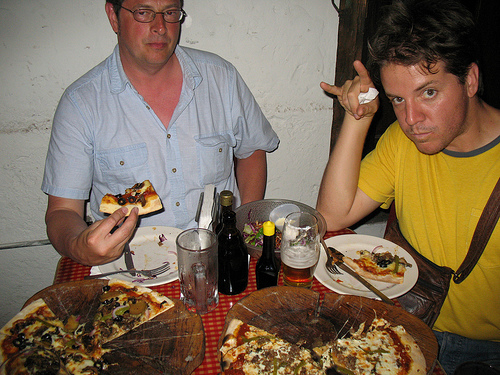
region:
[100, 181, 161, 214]
pizza is half eaten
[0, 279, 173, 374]
some pieces of pizza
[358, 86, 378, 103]
the napkin is white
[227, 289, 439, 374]
pizza tray is black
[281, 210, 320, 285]
a glass of beer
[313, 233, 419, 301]
the plate is white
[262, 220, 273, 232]
the cap is yellow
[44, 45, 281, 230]
shirt is light blue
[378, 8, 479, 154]
man looking at camera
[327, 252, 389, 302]
knife on the plate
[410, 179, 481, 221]
man wearing a yellow shirt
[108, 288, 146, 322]
a slice of pizza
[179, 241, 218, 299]
a clear glass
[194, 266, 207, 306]
handle on the glass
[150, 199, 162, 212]
crust of the pizza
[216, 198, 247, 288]
a black bottle on the table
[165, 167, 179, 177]
button on the shirt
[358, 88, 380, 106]
a white napkin in hand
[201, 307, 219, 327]
the red table cloth on the table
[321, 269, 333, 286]
a white plate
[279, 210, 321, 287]
Glass of beer is mostly empty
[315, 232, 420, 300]
Plate with knife and fork and some half eaten pizza.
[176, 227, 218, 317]
Dirty empty glass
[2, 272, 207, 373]
Vegetable pizza on a wooden cutting board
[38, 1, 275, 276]
Man in a blue shirt is eating pizza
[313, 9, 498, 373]
Man in a yellow shirt is eating pizza and doing a hand gesture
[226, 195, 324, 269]
Metal bowl of salad behind beer glass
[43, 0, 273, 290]
Man is wearing glasses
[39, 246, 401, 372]
Red checkered table cloth under plates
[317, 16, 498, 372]
Man is wearing a brown leather bag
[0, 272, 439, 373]
Two wooden trays of pizza.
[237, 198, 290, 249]
A glass bowl of tossed salad.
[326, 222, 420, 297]
A white dish with half eaten pizza.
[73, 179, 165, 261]
A hand holding a half eaten pizza.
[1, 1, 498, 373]
Two men sitting at a table.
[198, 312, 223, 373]
A red table cloth of plaid design.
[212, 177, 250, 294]
A beverage in a dark bottle.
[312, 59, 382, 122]
A rock and roll hand sign.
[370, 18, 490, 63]
The man's brown curly hair.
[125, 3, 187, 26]
The man's dark rimmer glasses.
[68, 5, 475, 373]
two men are sitting at the table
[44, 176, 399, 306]
the man are eating pizza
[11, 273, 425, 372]
two separate pizzas are at the table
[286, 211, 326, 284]
the man has a glass of beer with his pizza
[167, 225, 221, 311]
the glass is empty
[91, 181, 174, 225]
the man is holding a slice of pizza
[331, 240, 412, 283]
a slice of pizza is on the plate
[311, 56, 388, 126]
the man is giving one of the "rock and roll" gestures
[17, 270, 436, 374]
the pizzas are placed on wooden plates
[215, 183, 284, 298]
three glass bottles sit at the table